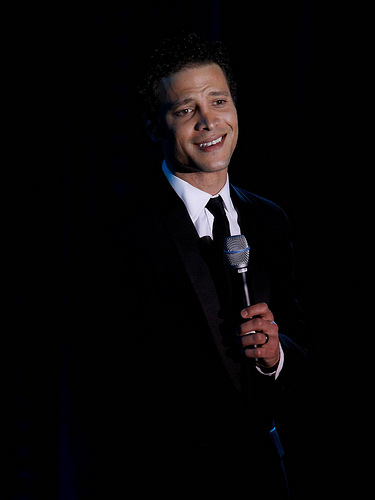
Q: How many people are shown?
A: One.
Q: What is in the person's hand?
A: Microphone.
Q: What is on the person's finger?
A: Ring.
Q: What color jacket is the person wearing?
A: Black.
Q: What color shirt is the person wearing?
A: White.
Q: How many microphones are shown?
A: 1.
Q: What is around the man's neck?
A: Tie.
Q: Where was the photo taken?
A: On a stage.